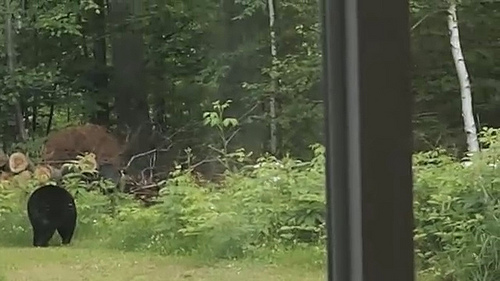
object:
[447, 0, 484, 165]
trees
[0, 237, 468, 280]
field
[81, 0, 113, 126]
tree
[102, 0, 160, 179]
tree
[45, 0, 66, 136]
tree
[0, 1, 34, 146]
tree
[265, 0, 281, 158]
trunk